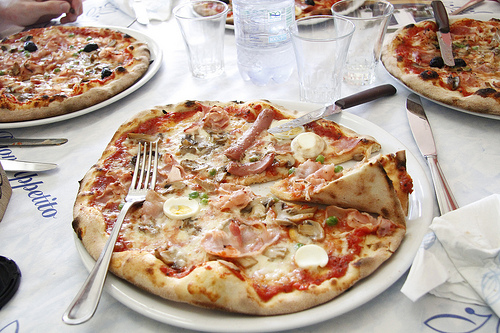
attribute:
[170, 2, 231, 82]
cup — empty, plastic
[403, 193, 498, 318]
napkin — blue, white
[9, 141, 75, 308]
tablecloth — white, blue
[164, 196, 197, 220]
egg — topping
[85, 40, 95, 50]
olive — toppings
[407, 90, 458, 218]
knife — butter, silver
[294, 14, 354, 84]
glass — shot, clear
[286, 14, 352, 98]
glass — shot, clear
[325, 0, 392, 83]
glass — shot, clear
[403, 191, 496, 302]
napkin — white, folded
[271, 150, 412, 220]
slice — pizza, bent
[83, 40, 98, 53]
olive — sliced, black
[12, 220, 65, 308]
tablecloth — white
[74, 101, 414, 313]
pizza — cheese, large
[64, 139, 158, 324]
fork — dinner, silver, metal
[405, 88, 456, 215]
knife — metal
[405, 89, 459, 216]
metal — silver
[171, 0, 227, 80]
cup — empty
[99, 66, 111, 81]
olive — black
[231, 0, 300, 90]
bottle — plastic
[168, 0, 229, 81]
glass — empty, clear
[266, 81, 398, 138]
knife — steak, black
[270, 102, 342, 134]
blade — metal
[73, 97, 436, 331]
plate — white, ceramic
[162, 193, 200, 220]
mushroom — white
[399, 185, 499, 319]
napkin — white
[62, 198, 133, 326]
handle — long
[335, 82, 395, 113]
handle — wooden, brown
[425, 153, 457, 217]
handle — metal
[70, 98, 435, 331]
dish — white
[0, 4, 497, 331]
cloth — white